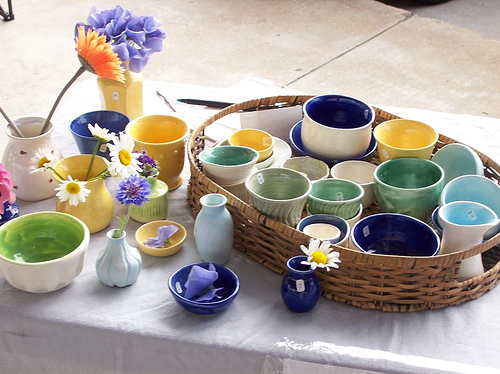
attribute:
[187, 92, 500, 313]
basket — wicker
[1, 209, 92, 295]
bowl — white, round, green inside, empty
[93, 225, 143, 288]
vase — white, small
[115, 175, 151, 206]
flower — blue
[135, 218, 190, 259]
bowl — small, yellow, round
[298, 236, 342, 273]
daisy — white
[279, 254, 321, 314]
container — dark blue, blue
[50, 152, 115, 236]
container — yellow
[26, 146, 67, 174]
daisy — white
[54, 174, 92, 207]
daisy — white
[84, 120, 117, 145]
daisy — white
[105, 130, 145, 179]
flower — white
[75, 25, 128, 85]
sunflower — orange, long stemmed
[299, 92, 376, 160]
container — white, blue inside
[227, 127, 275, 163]
container — yellow, small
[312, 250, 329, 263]
center — yellow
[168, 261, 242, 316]
bowl — round, dark blue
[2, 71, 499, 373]
table cloth — white, plastic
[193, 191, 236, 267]
vase — slender, light blue, blue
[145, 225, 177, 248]
petal — pastel purple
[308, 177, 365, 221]
bowl — green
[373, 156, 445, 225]
vase — green